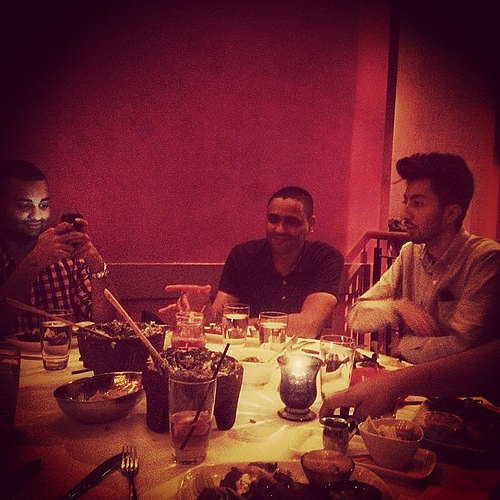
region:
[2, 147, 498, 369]
three men sitting around a table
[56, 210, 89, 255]
little black cell phone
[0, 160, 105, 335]
man seated with blue and white plaid shirt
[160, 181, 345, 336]
man seated with black t-shirt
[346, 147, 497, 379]
man seated with gray sweater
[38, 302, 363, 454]
a bunch of water glasses on table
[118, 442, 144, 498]
gray metal fork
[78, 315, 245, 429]
two black food bowls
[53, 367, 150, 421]
gray metal bowl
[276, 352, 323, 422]
little candle in a cup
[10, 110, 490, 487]
The friends are enjoying a meal together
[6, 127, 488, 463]
The friends are having a celebration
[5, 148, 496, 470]
Food is prepared on a table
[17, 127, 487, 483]
Friends are talking while eating dinner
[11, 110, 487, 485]
Friends are gathered for the evening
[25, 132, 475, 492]
Silverware is on the table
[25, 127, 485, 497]
Drinking glasses are on the table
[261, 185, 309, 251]
A man has a smile on his face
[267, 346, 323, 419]
A candle is on a table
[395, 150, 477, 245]
A man has dark colored hair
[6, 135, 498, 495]
Three men at a table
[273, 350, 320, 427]
A candle on a table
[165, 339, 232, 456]
A glass with a straw in it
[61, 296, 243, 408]
Bowls of food on the table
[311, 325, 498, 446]
A persons hand on the table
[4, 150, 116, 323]
A man looking at a phone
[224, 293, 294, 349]
Two glasses of water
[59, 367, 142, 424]
A stainless steel bowl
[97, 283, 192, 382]
A spoon in a bowl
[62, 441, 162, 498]
A knife and a fork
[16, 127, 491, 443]
people sitting at a table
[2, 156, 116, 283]
man looking at his phone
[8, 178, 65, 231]
light from the phone on the man`s face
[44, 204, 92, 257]
man is holding a phone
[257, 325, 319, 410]
candle on the table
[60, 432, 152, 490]
knife and fork on the table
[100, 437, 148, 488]
the fork is silver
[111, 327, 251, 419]
salad bowl on the table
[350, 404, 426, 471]
a cup of butter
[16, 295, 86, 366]
a glass of water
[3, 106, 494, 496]
3 young gentlement seated around a dinner table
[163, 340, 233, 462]
Half empty glass with a straw on table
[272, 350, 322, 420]
Lit candle ambiance on table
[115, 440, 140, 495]
stainless steel fork laying on table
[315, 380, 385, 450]
Richt hand reaching for small metalic creme pitcher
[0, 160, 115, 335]
Man staring at telephone screen in shadows, face lit.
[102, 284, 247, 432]
Tall heaping bowl of food with wooden serving spoon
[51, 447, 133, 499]
Metal butter knife on table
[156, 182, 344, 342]
Man seated at dinner table motioning with right hand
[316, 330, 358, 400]
Empty water glass